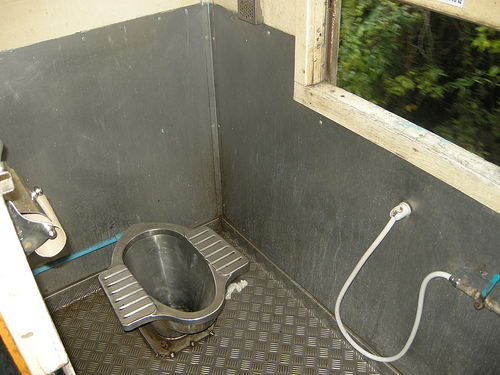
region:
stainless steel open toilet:
[103, 246, 210, 333]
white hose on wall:
[341, 250, 446, 350]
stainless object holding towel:
[7, 168, 64, 244]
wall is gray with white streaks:
[264, 164, 330, 266]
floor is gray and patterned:
[265, 325, 297, 362]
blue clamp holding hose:
[473, 265, 491, 310]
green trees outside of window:
[401, 93, 481, 161]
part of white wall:
[11, 288, 61, 359]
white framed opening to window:
[422, 120, 484, 178]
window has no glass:
[410, 85, 477, 140]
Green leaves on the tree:
[346, 56, 368, 76]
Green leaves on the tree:
[350, 74, 400, 106]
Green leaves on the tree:
[398, 61, 462, 96]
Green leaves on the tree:
[353, 6, 404, 49]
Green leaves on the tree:
[460, 26, 497, 56]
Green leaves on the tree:
[462, 58, 492, 101]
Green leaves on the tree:
[452, 104, 492, 150]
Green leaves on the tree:
[414, 62, 466, 115]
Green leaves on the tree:
[373, 32, 433, 132]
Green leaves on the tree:
[445, 63, 485, 171]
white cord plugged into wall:
[315, 191, 494, 373]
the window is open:
[305, 2, 495, 187]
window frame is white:
[282, 5, 497, 242]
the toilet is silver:
[62, 205, 279, 338]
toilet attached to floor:
[69, 228, 263, 350]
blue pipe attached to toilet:
[27, 223, 127, 283]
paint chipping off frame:
[310, 2, 335, 81]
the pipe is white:
[18, 185, 90, 275]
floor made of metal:
[40, 265, 379, 374]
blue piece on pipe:
[467, 262, 497, 313]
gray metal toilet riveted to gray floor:
[98, 217, 250, 345]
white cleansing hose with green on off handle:
[329, 199, 494, 369]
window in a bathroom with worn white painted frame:
[292, 0, 492, 217]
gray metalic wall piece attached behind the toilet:
[0, 2, 225, 227]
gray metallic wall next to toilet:
[212, 10, 479, 368]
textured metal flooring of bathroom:
[219, 285, 346, 373]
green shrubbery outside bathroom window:
[337, 1, 489, 151]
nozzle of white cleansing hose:
[384, 199, 415, 226]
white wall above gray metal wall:
[4, 0, 124, 56]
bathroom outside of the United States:
[5, 5, 485, 369]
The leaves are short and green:
[347, 13, 395, 85]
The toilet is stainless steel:
[95, 213, 256, 362]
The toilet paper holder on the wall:
[1, 151, 73, 257]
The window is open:
[275, 19, 495, 182]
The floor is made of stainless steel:
[220, 315, 334, 371]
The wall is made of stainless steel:
[57, 80, 197, 196]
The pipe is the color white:
[333, 196, 446, 363]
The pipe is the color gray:
[453, 274, 498, 326]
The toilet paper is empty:
[17, 173, 80, 265]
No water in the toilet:
[131, 236, 216, 326]